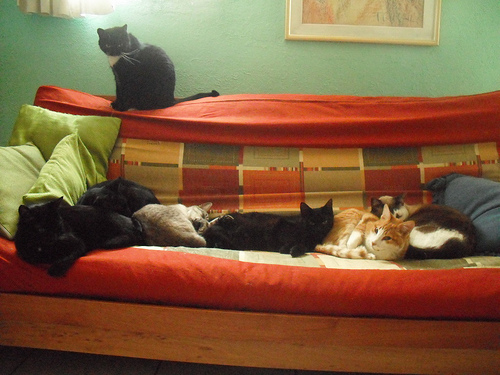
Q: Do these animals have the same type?
A: Yes, all the animals are cats.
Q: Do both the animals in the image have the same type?
A: Yes, all the animals are cats.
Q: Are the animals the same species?
A: Yes, all the animals are cats.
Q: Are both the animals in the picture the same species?
A: Yes, all the animals are cats.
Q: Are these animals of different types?
A: No, all the animals are cats.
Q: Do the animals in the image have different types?
A: No, all the animals are cats.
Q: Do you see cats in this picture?
A: Yes, there is a cat.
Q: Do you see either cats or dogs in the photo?
A: Yes, there is a cat.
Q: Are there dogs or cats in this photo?
A: Yes, there is a cat.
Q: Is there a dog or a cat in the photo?
A: Yes, there is a cat.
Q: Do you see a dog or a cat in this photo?
A: Yes, there is a cat.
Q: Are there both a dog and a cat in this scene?
A: No, there is a cat but no dogs.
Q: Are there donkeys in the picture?
A: No, there are no donkeys.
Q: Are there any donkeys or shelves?
A: No, there are no donkeys or shelves.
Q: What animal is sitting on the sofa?
A: The cat is sitting on the sofa.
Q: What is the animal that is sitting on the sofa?
A: The animal is a cat.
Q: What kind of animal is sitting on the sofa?
A: The animal is a cat.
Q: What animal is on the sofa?
A: The cat is on the sofa.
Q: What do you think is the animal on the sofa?
A: The animal is a cat.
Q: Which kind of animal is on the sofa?
A: The animal is a cat.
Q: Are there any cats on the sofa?
A: Yes, there is a cat on the sofa.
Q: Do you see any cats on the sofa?
A: Yes, there is a cat on the sofa.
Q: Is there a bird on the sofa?
A: No, there is a cat on the sofa.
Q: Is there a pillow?
A: Yes, there is a pillow.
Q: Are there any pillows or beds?
A: Yes, there is a pillow.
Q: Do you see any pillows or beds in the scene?
A: Yes, there is a pillow.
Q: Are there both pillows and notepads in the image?
A: No, there is a pillow but no notepads.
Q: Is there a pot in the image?
A: No, there are no pots.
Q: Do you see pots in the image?
A: No, there are no pots.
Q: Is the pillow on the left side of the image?
A: Yes, the pillow is on the left of the image.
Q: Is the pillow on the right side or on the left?
A: The pillow is on the left of the image.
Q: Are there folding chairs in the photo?
A: No, there are no folding chairs.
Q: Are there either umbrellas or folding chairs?
A: No, there are no folding chairs or umbrellas.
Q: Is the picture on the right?
A: Yes, the picture is on the right of the image.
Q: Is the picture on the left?
A: No, the picture is on the right of the image.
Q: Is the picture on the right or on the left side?
A: The picture is on the right of the image.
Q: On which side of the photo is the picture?
A: The picture is on the right of the image.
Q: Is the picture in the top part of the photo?
A: Yes, the picture is in the top of the image.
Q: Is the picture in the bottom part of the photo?
A: No, the picture is in the top of the image.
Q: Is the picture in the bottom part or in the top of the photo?
A: The picture is in the top of the image.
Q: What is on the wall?
A: The picture is on the wall.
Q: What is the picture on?
A: The picture is on the wall.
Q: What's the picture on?
A: The picture is on the wall.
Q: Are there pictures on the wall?
A: Yes, there is a picture on the wall.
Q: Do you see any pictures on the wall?
A: Yes, there is a picture on the wall.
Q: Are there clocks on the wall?
A: No, there is a picture on the wall.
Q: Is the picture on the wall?
A: Yes, the picture is on the wall.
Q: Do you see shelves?
A: No, there are no shelves.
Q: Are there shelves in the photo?
A: No, there are no shelves.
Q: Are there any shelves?
A: No, there are no shelves.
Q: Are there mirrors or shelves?
A: No, there are no shelves or mirrors.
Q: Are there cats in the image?
A: Yes, there is a cat.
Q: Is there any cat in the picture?
A: Yes, there is a cat.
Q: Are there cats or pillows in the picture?
A: Yes, there is a cat.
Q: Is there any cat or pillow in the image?
A: Yes, there is a cat.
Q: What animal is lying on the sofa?
A: The cat is lying on the sofa.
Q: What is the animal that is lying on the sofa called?
A: The animal is a cat.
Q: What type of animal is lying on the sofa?
A: The animal is a cat.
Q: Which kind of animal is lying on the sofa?
A: The animal is a cat.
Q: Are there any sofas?
A: Yes, there is a sofa.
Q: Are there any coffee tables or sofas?
A: Yes, there is a sofa.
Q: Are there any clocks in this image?
A: No, there are no clocks.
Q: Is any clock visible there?
A: No, there are no clocks.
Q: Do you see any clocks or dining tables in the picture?
A: No, there are no clocks or dining tables.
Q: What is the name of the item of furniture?
A: The piece of furniture is a sofa.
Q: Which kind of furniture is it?
A: The piece of furniture is a sofa.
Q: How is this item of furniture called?
A: This is a sofa.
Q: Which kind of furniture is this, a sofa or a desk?
A: This is a sofa.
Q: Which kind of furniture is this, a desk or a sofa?
A: This is a sofa.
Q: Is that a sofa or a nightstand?
A: That is a sofa.